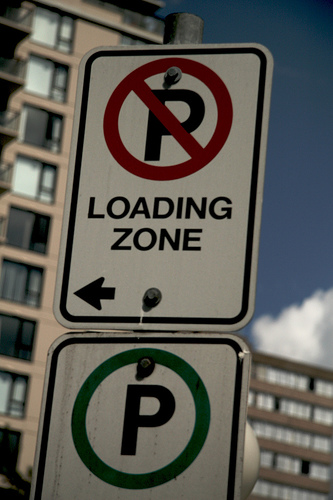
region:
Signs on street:
[19, 25, 282, 498]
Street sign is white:
[32, 32, 291, 332]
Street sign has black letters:
[18, 29, 292, 335]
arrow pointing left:
[64, 271, 122, 318]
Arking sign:
[3, 327, 285, 499]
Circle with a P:
[61, 344, 218, 497]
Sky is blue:
[266, 11, 331, 291]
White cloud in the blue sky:
[251, 277, 329, 358]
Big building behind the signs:
[0, 3, 105, 496]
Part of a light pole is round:
[242, 421, 270, 499]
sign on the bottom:
[24, 331, 249, 498]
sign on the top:
[54, 46, 256, 329]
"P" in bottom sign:
[119, 379, 175, 461]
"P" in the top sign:
[143, 87, 204, 160]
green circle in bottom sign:
[73, 346, 210, 488]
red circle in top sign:
[103, 56, 231, 179]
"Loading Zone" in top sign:
[85, 192, 232, 253]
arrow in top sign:
[73, 274, 113, 310]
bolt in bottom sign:
[134, 354, 152, 371]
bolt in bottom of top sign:
[140, 286, 163, 306]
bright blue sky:
[277, 132, 327, 304]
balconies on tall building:
[4, 1, 29, 71]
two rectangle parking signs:
[89, 31, 226, 402]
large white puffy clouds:
[279, 263, 330, 364]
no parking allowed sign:
[129, 65, 234, 189]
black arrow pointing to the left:
[81, 267, 126, 325]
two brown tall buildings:
[14, 253, 313, 445]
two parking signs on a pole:
[137, 18, 218, 487]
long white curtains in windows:
[27, 12, 49, 97]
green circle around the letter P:
[85, 353, 192, 491]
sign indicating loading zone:
[53, 36, 276, 316]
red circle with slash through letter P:
[98, 53, 236, 183]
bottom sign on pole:
[34, 330, 250, 498]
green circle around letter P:
[69, 345, 207, 489]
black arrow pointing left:
[73, 269, 124, 311]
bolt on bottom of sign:
[139, 285, 168, 311]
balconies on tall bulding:
[2, 6, 36, 145]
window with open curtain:
[290, 453, 319, 477]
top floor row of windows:
[256, 363, 304, 387]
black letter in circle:
[114, 378, 176, 459]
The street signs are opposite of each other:
[28, 45, 264, 498]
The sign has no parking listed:
[51, 43, 273, 330]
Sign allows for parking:
[24, 329, 250, 499]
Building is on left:
[0, 0, 177, 498]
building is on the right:
[248, 351, 332, 498]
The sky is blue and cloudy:
[154, 0, 331, 370]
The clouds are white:
[249, 286, 332, 372]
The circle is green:
[69, 347, 211, 489]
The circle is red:
[102, 56, 233, 180]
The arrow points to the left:
[72, 274, 119, 312]